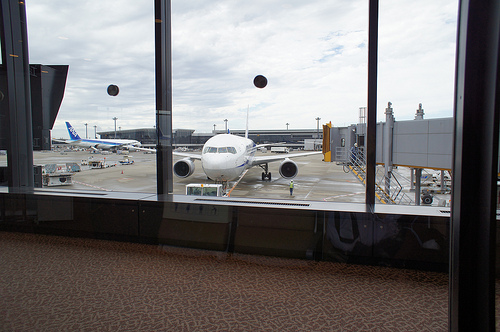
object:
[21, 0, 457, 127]
sky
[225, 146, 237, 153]
window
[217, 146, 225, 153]
window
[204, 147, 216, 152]
window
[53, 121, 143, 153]
airplane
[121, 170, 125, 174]
cone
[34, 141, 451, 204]
ground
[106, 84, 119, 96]
magnet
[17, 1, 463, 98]
clouds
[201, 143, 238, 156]
cockpit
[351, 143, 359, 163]
worker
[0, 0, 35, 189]
magnet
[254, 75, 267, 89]
magnet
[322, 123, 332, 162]
trim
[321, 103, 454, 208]
gate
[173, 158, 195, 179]
engine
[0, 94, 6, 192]
window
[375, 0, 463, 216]
window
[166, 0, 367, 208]
window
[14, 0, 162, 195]
window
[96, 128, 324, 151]
building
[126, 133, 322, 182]
airplane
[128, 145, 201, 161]
wing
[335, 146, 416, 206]
staris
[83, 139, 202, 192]
runway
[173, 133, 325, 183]
plane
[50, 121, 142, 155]
plane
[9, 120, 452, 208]
tarmac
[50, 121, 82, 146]
tail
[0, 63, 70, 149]
light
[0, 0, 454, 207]
airport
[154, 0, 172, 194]
metal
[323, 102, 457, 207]
walkway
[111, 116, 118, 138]
light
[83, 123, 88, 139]
light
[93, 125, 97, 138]
light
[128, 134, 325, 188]
plane